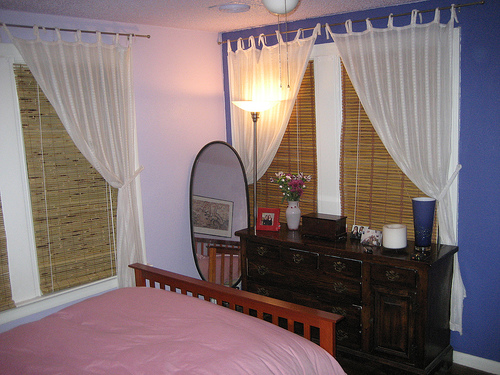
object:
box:
[301, 212, 349, 240]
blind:
[236, 59, 315, 226]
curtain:
[15, 29, 148, 291]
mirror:
[190, 140, 250, 289]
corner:
[195, 28, 264, 152]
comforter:
[0, 293, 348, 375]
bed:
[0, 262, 344, 373]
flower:
[291, 187, 305, 195]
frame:
[256, 207, 280, 232]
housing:
[0, 0, 500, 375]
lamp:
[232, 100, 276, 113]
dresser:
[226, 229, 459, 366]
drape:
[76, 31, 146, 122]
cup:
[411, 196, 437, 251]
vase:
[286, 200, 301, 231]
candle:
[381, 223, 408, 256]